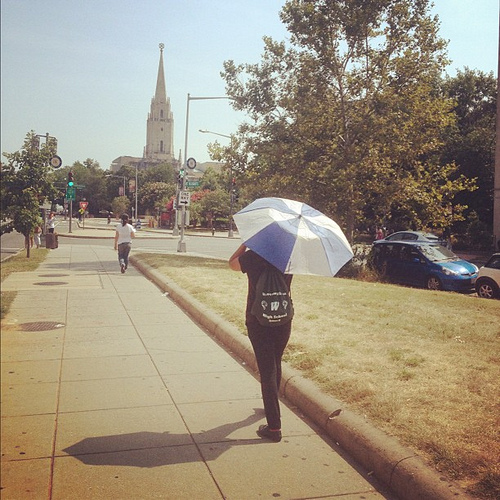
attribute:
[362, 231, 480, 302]
car — blue, parked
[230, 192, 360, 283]
umbrella — womans, blue, white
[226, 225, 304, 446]
girl — walking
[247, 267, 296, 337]
backpack — small, writing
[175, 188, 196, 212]
sign — traffic, pointing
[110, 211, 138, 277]
people — standing, waiting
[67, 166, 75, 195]
signal — green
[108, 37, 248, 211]
building — cathedral, tall, old